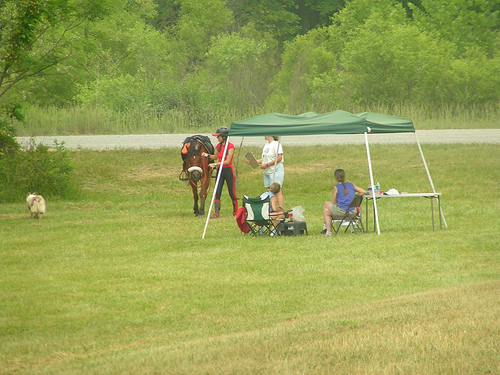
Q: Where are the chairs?
A: Under the canopy.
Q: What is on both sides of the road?
A: Grass.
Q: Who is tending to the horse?
A: The woman in red.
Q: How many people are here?
A: Four.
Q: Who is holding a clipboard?
A: The woman with yellow shirt.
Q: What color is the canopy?
A: Green.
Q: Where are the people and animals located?
A: Green field.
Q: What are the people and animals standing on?
A: Grass.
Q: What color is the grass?
A: Green.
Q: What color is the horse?
A: Brown.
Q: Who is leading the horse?
A: A man.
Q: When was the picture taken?
A: During the day.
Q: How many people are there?
A: 4.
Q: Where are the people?
A: In a park.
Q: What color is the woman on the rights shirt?
A: Blue.